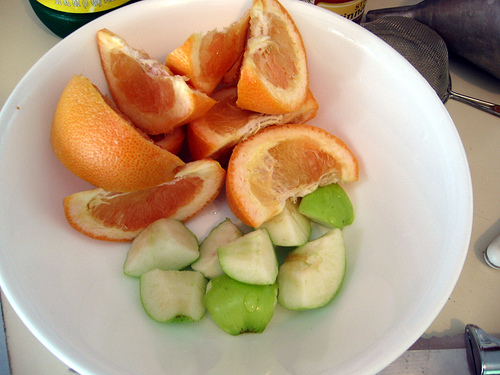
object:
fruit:
[52, 0, 359, 336]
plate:
[0, 0, 477, 375]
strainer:
[358, 15, 500, 117]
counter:
[1, 0, 500, 374]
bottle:
[302, 0, 366, 27]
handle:
[484, 235, 500, 270]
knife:
[407, 332, 497, 350]